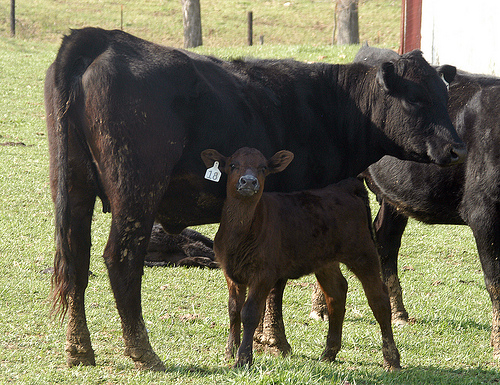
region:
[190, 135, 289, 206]
numbered tag on ear of a calf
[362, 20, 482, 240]
face of a cow against the body of another cow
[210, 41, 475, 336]
adult cow in back of a calf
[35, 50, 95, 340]
cow tail hanging down with pointy strands at end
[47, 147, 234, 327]
animal laying down in back of standing animals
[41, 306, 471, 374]
animal legs on top of green grass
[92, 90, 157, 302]
nicks and dents on the leg of a cow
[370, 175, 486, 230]
curved underside of a farm animal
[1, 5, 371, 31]
various size posts on the edge of the fence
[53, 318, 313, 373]
irregular knobs and protrusions on cow legs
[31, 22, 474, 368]
CALF STANDING NEXT TO BIG COW.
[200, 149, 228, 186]
TAG 18 ON CALF'S EAR.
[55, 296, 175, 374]
DIRTY COW HOOVES COVERED IN MUD.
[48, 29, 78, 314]
LONG COW TAIL ALMOST TOUCHING THE GROUND.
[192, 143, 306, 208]
CALF LOOKING TOWARDS THE CAMERA.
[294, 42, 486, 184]
COW LOOKING AWAY FROM CAMERA.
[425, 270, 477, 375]
LUSH GREEN GRASS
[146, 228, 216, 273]
COW LAYING ON THE GROUND.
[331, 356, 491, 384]
COW SHADOW ON GROUND.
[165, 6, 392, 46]
FENCE AROUND COWS.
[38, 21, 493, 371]
Cows standing in pasture.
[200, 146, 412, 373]
Baby calf next to mother.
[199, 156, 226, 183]
Tag in calf ear.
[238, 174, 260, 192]
Calf nose and mouth.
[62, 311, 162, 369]
A cow's muddy hooves.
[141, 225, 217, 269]
Cow lying on ground.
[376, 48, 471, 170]
Head of a cow.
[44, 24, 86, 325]
A cow's long tail.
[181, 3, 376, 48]
Posts nailed to fence.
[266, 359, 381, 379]
Grass inside pasture.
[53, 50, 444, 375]
Calf under large cow.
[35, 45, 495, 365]
Three standing cows in field.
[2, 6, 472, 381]
Field with short grass.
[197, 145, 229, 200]
Calf ear with tag.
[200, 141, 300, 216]
Calf head looking forward.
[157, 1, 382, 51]
Tree trunks near fence.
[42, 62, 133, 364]
Long tail on black cow.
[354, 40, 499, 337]
Black cow head obstructing view of standing cow.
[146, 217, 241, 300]
Cow reclining on grass.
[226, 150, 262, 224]
Black nose on brown calf's face.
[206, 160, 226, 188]
Tag on cow's ear.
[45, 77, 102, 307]
Black tail on cow.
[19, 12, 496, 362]
Three black cows.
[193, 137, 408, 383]
One black baby cow.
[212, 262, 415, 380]
Four legs on baby cow.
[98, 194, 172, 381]
A black cow leg.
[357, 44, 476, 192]
A black cow head.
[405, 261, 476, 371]
Green grass on ground.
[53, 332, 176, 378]
Two feet on a cow.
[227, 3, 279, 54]
One brown fence post.